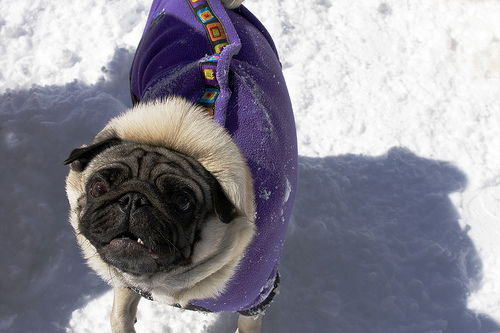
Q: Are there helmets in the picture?
A: No, there are no helmets.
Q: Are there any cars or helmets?
A: No, there are no helmets or cars.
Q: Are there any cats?
A: No, there are no cats.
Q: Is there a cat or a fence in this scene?
A: No, there are no cats or fences.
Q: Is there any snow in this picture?
A: Yes, there is snow.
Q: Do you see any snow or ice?
A: Yes, there is snow.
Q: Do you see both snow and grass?
A: No, there is snow but no grass.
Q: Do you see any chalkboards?
A: No, there are no chalkboards.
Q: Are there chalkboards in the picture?
A: No, there are no chalkboards.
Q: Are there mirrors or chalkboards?
A: No, there are no chalkboards or mirrors.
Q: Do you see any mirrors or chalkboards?
A: No, there are no chalkboards or mirrors.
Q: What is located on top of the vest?
A: The snow is on top of the vest.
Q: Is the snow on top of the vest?
A: Yes, the snow is on top of the vest.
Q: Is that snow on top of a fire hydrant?
A: No, the snow is on top of the vest.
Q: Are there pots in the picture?
A: No, there are no pots.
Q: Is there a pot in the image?
A: No, there are no pots.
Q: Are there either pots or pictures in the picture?
A: No, there are no pots or pictures.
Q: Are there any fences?
A: No, there are no fences.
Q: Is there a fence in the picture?
A: No, there are no fences.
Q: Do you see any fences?
A: No, there are no fences.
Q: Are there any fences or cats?
A: No, there are no cats or fences.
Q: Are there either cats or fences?
A: No, there are no cats or fences.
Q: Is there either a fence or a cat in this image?
A: No, there are no cats or fences.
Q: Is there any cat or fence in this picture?
A: No, there are no cats or fences.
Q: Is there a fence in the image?
A: No, there are no fences.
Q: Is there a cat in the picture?
A: No, there are no cats.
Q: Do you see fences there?
A: No, there are no fences.